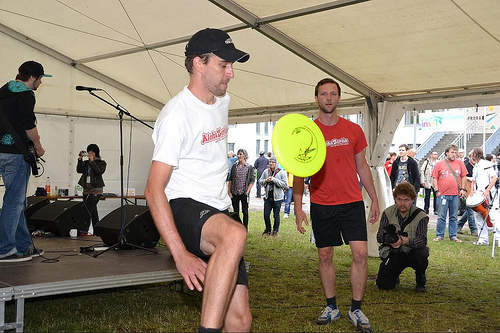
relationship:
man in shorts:
[295, 70, 378, 326] [301, 198, 376, 257]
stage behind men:
[4, 158, 224, 314] [161, 16, 407, 332]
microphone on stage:
[65, 73, 141, 156] [4, 158, 224, 314]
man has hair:
[295, 70, 378, 326] [304, 70, 341, 96]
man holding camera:
[295, 70, 378, 326] [374, 214, 409, 255]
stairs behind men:
[405, 113, 499, 178] [161, 16, 407, 332]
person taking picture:
[369, 179, 442, 283] [380, 222, 410, 245]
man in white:
[295, 70, 378, 326] [150, 89, 227, 182]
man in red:
[295, 70, 378, 326] [322, 138, 359, 181]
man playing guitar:
[295, 70, 378, 326] [16, 122, 63, 179]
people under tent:
[131, 30, 493, 320] [9, 3, 497, 100]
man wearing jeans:
[2, 50, 59, 263] [2, 151, 56, 266]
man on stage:
[2, 50, 59, 263] [4, 158, 224, 314]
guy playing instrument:
[2, 50, 59, 263] [16, 122, 63, 179]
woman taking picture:
[67, 139, 110, 205] [380, 222, 410, 245]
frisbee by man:
[268, 111, 341, 173] [295, 70, 378, 326]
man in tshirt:
[295, 70, 378, 326] [287, 113, 380, 221]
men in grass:
[161, 16, 407, 332] [242, 211, 485, 322]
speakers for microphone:
[27, 188, 165, 256] [65, 73, 141, 156]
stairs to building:
[405, 113, 499, 178] [378, 110, 498, 211]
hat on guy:
[16, 57, 61, 81] [2, 50, 59, 263]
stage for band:
[4, 158, 224, 314] [0, 56, 134, 270]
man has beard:
[295, 70, 378, 326] [322, 104, 339, 114]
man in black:
[295, 70, 378, 326] [0, 85, 47, 168]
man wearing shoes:
[295, 70, 378, 326] [317, 294, 379, 327]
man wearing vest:
[295, 70, 378, 326] [379, 205, 429, 256]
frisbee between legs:
[268, 111, 341, 173] [181, 185, 285, 333]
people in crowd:
[131, 30, 493, 320] [231, 127, 497, 250]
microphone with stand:
[65, 73, 141, 156] [105, 112, 151, 229]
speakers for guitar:
[27, 188, 165, 256] [16, 122, 63, 179]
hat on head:
[16, 57, 61, 81] [6, 60, 57, 93]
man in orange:
[295, 70, 378, 326] [432, 152, 481, 210]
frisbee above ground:
[268, 111, 341, 173] [289, 227, 375, 305]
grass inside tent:
[242, 211, 485, 322] [9, 3, 497, 100]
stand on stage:
[105, 112, 151, 229] [4, 158, 224, 314]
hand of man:
[166, 237, 223, 296] [295, 70, 378, 326]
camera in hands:
[374, 214, 409, 255] [373, 222, 423, 264]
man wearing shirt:
[295, 70, 378, 326] [141, 77, 252, 219]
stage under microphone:
[4, 158, 224, 314] [65, 73, 141, 156]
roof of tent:
[40, 20, 480, 81] [9, 3, 497, 100]